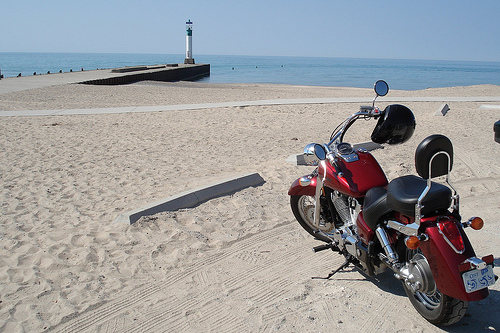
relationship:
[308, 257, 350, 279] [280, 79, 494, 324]
kick stand on motorcycle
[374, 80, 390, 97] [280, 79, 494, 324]
mirror on motorcycle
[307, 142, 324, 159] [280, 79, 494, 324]
mirror on motorcycle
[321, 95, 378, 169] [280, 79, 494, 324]
handlebar on motorcycle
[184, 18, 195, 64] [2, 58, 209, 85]
light house on pier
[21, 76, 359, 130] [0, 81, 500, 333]
sidewalk running through beach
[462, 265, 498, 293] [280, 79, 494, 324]
license plate on motorcycle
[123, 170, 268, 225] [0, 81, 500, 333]
curb market in beach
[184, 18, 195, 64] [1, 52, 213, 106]
light house at end of pier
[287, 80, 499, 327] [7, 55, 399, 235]
motorcycle parked off beach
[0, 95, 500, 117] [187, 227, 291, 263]
sidewalk through beach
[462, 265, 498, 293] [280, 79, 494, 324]
license plate at rear of motorcycle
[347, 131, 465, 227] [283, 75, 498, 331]
seat at rear of motorcycle's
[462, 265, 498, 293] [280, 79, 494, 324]
license plate on back of motorcycle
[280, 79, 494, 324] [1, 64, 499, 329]
motorcycle on beach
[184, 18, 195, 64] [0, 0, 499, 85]
light house near ocean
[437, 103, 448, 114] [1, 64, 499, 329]
concrete block on beach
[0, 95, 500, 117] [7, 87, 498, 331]
sidewalk on beach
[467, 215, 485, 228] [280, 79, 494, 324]
light on back of motorcycle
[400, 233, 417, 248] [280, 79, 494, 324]
light on back of motorcycle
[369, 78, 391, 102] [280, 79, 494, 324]
mirror on motorcycle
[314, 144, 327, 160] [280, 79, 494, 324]
mirror on motorcycle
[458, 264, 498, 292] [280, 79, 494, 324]
license plate on motorcycle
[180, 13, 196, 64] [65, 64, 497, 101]
light house on beach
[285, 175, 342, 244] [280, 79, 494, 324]
tire on motorcycle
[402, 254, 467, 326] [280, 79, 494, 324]
rear wheel on motorcycle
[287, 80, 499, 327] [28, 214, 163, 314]
motorcycle in sand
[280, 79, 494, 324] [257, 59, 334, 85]
motorcycle parked near water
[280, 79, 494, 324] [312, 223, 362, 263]
motorcycle has brake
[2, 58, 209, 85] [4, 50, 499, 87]
pier leading into ocean